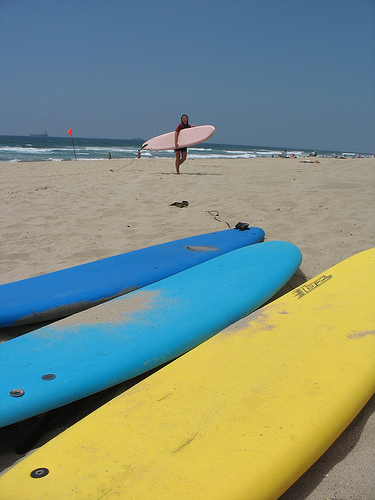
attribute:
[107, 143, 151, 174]
black — leash